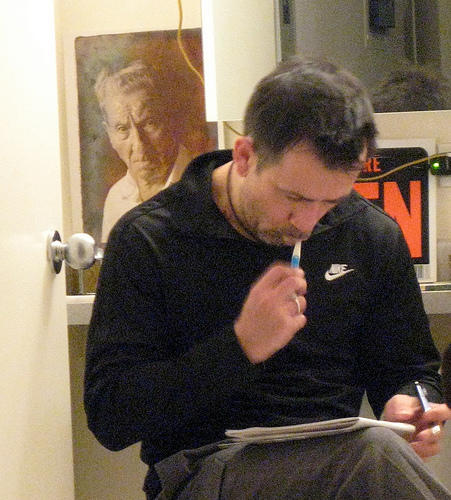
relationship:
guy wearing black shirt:
[83, 56, 449, 500] [82, 150, 444, 497]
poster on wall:
[70, 40, 227, 300] [55, 5, 203, 296]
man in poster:
[92, 55, 191, 267] [70, 40, 227, 300]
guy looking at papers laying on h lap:
[83, 56, 449, 500] [201, 401, 423, 500]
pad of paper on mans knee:
[223, 419, 369, 500] [344, 427, 418, 500]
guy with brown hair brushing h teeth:
[83, 56, 449, 500] [258, 253, 340, 373]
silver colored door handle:
[59, 214, 100, 307] [45, 226, 106, 273]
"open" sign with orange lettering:
[385, 174, 411, 250] [364, 158, 436, 278]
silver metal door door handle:
[49, 230, 96, 274] [50, 229, 104, 273]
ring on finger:
[292, 297, 301, 313] [281, 286, 309, 355]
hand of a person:
[238, 264, 314, 355] [133, 274, 327, 443]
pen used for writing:
[283, 230, 300, 275] [414, 355, 443, 433]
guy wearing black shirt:
[83, 56, 449, 500] [83, 149, 445, 483]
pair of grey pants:
[172, 453, 421, 480] [146, 425, 450, 499]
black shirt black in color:
[82, 150, 444, 497] [152, 246, 212, 391]